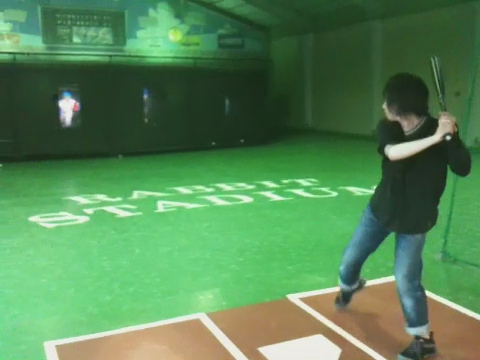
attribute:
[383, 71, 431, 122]
hair — long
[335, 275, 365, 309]
shoe — black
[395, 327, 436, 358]
shoe — black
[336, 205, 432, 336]
pants — blue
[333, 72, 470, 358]
boy — pale skinned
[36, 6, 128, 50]
sign — green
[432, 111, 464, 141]
hands — both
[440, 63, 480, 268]
batting cages — indoor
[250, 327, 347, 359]
homeplate — white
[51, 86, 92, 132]
pitcher — video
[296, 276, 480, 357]
dirt — brown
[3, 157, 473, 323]
floor — linoleum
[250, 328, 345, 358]
home plate — white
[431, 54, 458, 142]
bat — baseball, black, small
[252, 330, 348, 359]
base — white, baseball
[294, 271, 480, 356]
square — white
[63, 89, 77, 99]
helmet — baseball, dark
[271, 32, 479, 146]
wall — dark, green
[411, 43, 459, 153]
bat — black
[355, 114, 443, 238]
shirt — black